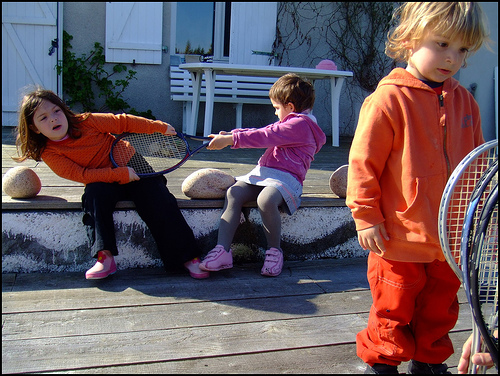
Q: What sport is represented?
A: Tennis.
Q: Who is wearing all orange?
A: Blonde child.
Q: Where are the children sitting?
A: On second deck.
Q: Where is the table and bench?
A: Against building.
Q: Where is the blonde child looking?
A: At rackets.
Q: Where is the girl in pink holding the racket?
A: Handle.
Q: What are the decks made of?
A: Wood.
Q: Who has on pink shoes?
A: The girls.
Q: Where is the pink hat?
A: On white table.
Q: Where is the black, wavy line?
A: Small wall.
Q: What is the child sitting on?
A: The deck.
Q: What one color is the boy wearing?
A: Orange.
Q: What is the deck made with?
A: Wood.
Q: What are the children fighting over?
A: A tennis racket.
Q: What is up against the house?
A: A bench.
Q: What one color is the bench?
A: White.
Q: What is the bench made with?
A: Wood.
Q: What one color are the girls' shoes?
A: Pink.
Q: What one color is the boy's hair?
A: Blonde.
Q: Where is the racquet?
A: Between the girls.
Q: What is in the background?
A: A building.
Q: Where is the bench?
A: Beneath the window.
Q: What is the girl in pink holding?
A: Tennis racket.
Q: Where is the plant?
A: Right of door.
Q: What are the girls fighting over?
A: Tennis racket.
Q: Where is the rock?
A: Between the kids.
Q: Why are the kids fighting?
A: For the racket.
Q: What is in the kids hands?
A: Racket.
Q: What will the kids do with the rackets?
A: Hit balls.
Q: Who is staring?
A: The boy.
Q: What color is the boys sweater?
A: Orange.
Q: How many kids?
A: 3.